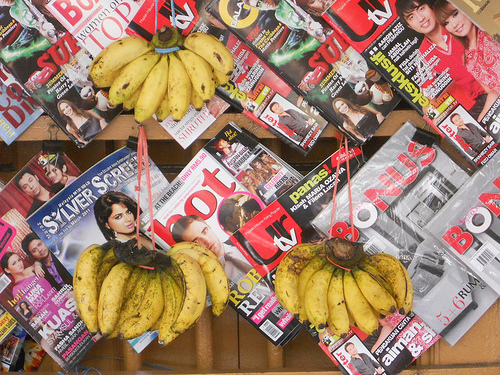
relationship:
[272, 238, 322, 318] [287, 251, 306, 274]
banana with spots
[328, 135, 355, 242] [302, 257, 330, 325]
string attached to banana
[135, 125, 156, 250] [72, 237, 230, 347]
string attached to bananas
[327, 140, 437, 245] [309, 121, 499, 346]
word on magazine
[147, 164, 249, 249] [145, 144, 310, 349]
wor on mag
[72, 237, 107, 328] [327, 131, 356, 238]
bananas hanging by string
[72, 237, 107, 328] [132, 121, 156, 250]
bananas hanging by string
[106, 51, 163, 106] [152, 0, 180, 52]
bananas hanging by string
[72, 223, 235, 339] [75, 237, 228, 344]
rot on banana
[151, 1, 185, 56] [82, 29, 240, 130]
string on bananas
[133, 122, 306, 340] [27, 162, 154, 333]
magazines on display magazines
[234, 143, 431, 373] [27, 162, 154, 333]
magazines on display magazines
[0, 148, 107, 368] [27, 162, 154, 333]
magazines on display magazines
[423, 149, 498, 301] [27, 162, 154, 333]
magazines on display magazines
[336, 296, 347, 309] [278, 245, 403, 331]
spot on bananas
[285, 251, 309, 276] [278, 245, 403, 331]
spot on bananas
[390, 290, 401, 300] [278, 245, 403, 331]
spot on bananas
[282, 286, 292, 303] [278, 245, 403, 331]
spot on bananas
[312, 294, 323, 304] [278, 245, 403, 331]
spot on bananas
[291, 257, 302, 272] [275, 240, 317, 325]
rot on banana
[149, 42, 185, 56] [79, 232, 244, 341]
tie around bananas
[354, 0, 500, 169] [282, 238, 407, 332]
magazine underneath bananas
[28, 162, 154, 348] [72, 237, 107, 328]
magazines underneath bananas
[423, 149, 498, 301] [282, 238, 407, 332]
magazines underneath bananas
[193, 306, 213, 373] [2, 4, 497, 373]
dowel on newstand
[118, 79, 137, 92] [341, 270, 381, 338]
rot on yellow banana